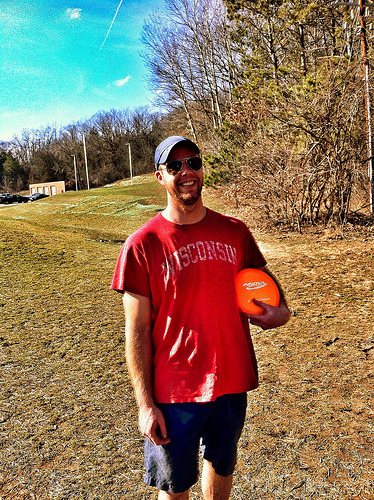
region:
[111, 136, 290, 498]
Man in red shirt with frisbee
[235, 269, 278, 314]
orange frisbee held by man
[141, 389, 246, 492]
blue shorts of man with frisbee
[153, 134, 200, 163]
blue cap of man with frisbee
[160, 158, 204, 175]
sunglasses of man with frisbee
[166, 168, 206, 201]
smile of man with frisbee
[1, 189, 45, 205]
several dark cars in background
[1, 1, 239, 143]
blue sky above a man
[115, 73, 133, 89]
white cloud in blue sky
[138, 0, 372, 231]
woods behind man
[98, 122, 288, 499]
Man standing in field with orange frisbee.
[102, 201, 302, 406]
Man dressed in red t-shirt.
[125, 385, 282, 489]
Man dressed in navy blue shorts.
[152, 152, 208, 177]
Man wearing sunglasses over eyes.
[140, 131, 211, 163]
Man wearing navy blue cap.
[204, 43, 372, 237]
Tall scrub bush growing on field.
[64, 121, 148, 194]
Light poles mounted behind brown building.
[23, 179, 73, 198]
Brown building with four doors.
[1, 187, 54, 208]
Cars parked in parking lot.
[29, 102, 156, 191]
Trees growing behind brown building.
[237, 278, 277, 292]
white words on orange frisbee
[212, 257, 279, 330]
round Frisbee in man's hand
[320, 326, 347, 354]
small piece of branch on ground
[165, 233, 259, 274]
faded words on red tee shirt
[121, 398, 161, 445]
veins in man's hand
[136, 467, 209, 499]
edge of blue shorts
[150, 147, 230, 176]
man wearing black sunglasses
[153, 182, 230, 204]
beard on man's face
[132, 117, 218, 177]
blue cap on man's head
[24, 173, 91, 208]
large brown building with white doors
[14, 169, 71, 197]
Storage building with white doors.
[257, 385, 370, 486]
Sticks ans dirt on ground.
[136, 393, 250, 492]
Pair of blue shorts.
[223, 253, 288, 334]
Orange and white frizbee.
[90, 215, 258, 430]
Red t-shirt that says wisconsin.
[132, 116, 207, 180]
Man wearing a blue hat.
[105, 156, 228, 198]
Man wearing sun glasses.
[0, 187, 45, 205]
Cars in a parking lot.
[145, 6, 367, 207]
A group of trees with and without leaves.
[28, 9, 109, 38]
Blue sky with white cloud.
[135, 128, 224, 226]
man wearing blue ball cap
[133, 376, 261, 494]
man wearing dark blue shorts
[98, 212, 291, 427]
man wearing red Wisconsin shirt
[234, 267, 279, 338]
fluorescent orange Frisbee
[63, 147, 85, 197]
light on top of metal pole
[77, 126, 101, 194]
light on top of metal pole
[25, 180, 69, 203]
brick building with four bay doors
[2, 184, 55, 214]
dark colored cars parked in parking lot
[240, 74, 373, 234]
tree with no leaves in the fall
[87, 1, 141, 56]
airplane exhaust in the blue sky